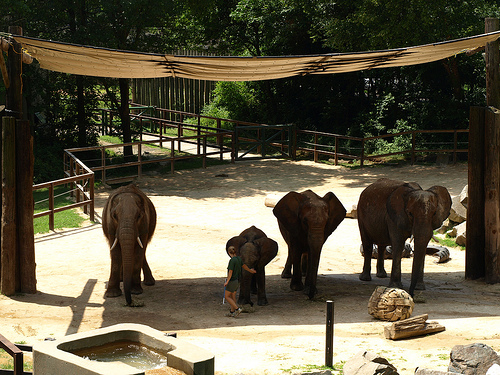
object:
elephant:
[356, 178, 453, 299]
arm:
[227, 259, 235, 282]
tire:
[360, 242, 413, 258]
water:
[91, 353, 98, 359]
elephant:
[272, 189, 346, 298]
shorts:
[225, 279, 239, 292]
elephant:
[226, 224, 276, 314]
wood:
[367, 286, 415, 322]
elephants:
[102, 183, 156, 304]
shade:
[8, 271, 500, 336]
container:
[32, 322, 214, 375]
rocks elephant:
[448, 184, 469, 223]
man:
[224, 246, 257, 318]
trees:
[1, 0, 499, 162]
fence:
[103, 100, 261, 161]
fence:
[32, 122, 471, 232]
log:
[383, 313, 446, 339]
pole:
[464, 18, 500, 285]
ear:
[144, 198, 150, 248]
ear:
[107, 196, 114, 242]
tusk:
[137, 237, 143, 248]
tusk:
[110, 238, 117, 250]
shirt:
[227, 256, 244, 281]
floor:
[242, 319, 304, 360]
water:
[117, 344, 133, 354]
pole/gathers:
[0, 26, 36, 296]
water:
[144, 357, 157, 368]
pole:
[324, 300, 334, 368]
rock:
[341, 351, 400, 375]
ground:
[201, 311, 296, 371]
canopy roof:
[0, 30, 500, 82]